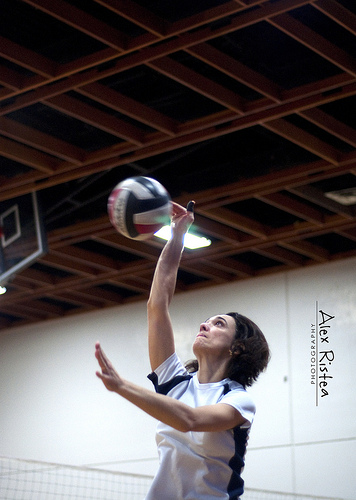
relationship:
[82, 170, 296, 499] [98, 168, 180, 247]
person hitting ball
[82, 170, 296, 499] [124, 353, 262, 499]
person in uniform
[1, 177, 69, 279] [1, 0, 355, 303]
hoop near ceiling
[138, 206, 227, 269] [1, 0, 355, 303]
light in ceiling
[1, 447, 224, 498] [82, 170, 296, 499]
net behind person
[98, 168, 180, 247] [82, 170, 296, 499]
ball near person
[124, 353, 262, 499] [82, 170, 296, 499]
uniform on person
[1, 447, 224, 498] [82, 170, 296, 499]
net near person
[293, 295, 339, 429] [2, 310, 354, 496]
logo on wall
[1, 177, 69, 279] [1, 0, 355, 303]
hoop in ceiling